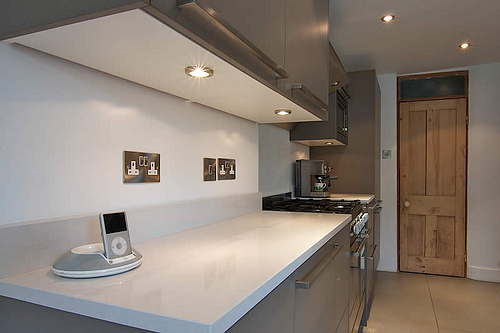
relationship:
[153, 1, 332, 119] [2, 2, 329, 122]
handles on cabinets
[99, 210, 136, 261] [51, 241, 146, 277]
ipod on trackpad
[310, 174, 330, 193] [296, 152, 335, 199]
pot on machine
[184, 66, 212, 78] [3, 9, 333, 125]
light beneath cabinet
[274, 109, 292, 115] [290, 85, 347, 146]
light beneath cabinet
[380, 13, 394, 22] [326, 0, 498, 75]
light on ceiling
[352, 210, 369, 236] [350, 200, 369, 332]
control dials on oven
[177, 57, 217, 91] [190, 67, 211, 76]
light on fixture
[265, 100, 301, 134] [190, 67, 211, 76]
light on fixture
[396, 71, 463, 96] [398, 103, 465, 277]
window above door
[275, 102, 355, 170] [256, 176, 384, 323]
microwave mounted above stove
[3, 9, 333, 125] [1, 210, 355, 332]
cabinet above counter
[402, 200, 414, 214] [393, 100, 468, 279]
knob on door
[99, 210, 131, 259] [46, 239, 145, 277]
ipod in speaker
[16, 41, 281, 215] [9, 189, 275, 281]
wall above backsplash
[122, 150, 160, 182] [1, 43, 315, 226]
picture hanging on wall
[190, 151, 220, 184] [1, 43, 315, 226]
picture hanging on wall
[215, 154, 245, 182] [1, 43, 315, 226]
picture hanging on wall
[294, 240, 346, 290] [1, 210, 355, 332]
handle below counter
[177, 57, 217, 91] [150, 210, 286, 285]
light above counter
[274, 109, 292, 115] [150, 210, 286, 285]
light above counter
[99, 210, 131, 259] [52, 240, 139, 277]
ipod plugged into speakers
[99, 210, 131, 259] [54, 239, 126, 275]
ipod in dock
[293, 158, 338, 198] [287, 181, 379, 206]
coffee maker on counter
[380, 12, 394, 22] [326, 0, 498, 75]
light on ceiling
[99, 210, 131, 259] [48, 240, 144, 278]
ipod on dock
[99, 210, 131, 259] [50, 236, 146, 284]
ipod plugged into dock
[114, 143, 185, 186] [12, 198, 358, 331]
plug above counter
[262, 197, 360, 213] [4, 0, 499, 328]
kitchen stove in kitchen